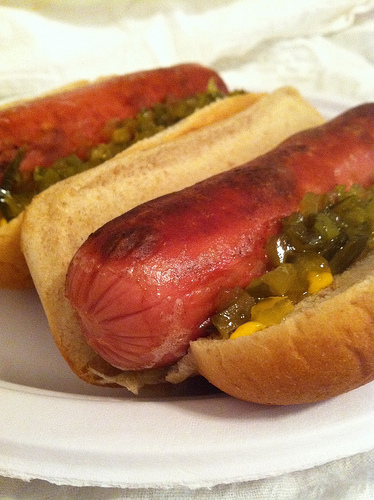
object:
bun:
[187, 256, 373, 409]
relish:
[257, 261, 295, 298]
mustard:
[230, 318, 265, 340]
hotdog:
[19, 86, 373, 407]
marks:
[217, 164, 299, 210]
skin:
[62, 103, 373, 374]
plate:
[0, 66, 373, 489]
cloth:
[0, 0, 373, 103]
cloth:
[0, 448, 373, 500]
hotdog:
[0, 61, 267, 292]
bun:
[0, 91, 276, 293]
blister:
[221, 158, 301, 208]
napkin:
[0, 1, 373, 106]